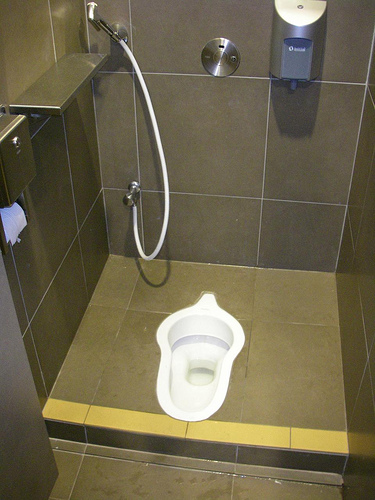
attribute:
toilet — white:
[141, 275, 244, 433]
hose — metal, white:
[95, 39, 182, 265]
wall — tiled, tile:
[62, 1, 267, 269]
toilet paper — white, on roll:
[3, 132, 43, 247]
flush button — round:
[197, 34, 247, 90]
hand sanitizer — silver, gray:
[267, 2, 333, 112]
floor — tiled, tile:
[68, 456, 304, 497]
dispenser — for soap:
[0, 112, 66, 249]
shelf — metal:
[26, 45, 117, 129]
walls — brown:
[22, 9, 147, 331]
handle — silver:
[82, 4, 124, 42]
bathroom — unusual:
[57, 178, 365, 478]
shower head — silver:
[79, 0, 120, 22]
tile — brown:
[246, 357, 347, 424]